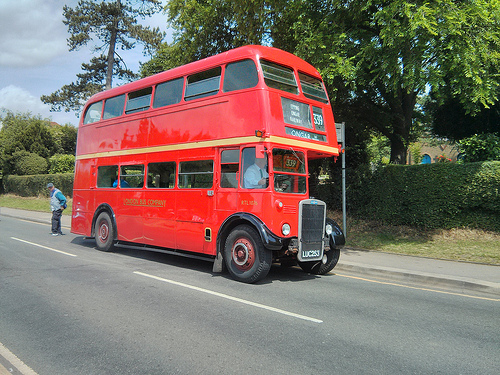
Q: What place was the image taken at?
A: It was taken at the road.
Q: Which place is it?
A: It is a road.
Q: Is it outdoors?
A: Yes, it is outdoors.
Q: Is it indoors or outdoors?
A: It is outdoors.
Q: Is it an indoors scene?
A: No, it is outdoors.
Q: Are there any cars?
A: No, there are no cars.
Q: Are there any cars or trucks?
A: No, there are no cars or trucks.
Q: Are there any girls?
A: No, there are no girls.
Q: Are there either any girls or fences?
A: No, there are no girls or fences.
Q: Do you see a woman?
A: No, there are no women.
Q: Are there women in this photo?
A: No, there are no women.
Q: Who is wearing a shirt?
A: The driver is wearing a shirt.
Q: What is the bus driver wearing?
A: The driver is wearing a shirt.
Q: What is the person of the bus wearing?
A: The driver is wearing a shirt.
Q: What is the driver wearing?
A: The driver is wearing a shirt.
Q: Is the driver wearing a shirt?
A: Yes, the driver is wearing a shirt.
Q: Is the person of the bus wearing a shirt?
A: Yes, the driver is wearing a shirt.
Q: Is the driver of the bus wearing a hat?
A: No, the driver is wearing a shirt.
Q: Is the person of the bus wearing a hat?
A: No, the driver is wearing a shirt.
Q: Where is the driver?
A: The driver is on the bus.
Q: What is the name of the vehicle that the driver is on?
A: The vehicle is a bus.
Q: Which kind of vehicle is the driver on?
A: The driver is on the bus.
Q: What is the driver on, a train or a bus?
A: The driver is on a bus.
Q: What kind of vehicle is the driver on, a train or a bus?
A: The driver is on a bus.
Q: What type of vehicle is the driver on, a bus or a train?
A: The driver is on a bus.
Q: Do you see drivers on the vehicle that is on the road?
A: Yes, there is a driver on the bus.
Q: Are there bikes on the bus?
A: No, there is a driver on the bus.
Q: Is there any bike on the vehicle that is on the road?
A: No, there is a driver on the bus.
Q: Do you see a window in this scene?
A: Yes, there is a window.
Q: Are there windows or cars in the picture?
A: Yes, there is a window.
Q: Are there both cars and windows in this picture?
A: No, there is a window but no cars.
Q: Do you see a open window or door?
A: Yes, there is an open window.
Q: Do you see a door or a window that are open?
A: Yes, the window is open.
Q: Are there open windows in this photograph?
A: Yes, there is an open window.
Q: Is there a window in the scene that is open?
A: Yes, there is a window that is open.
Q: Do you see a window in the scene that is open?
A: Yes, there is a window that is open.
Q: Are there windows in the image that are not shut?
A: Yes, there is a open window.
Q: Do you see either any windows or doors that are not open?
A: No, there is a window but it is open.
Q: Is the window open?
A: Yes, the window is open.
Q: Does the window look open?
A: Yes, the window is open.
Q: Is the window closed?
A: No, the window is open.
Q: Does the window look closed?
A: No, the window is open.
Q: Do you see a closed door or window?
A: No, there is a window but it is open.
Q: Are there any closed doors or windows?
A: No, there is a window but it is open.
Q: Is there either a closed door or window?
A: No, there is a window but it is open.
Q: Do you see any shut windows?
A: No, there is a window but it is open.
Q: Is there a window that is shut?
A: No, there is a window but it is open.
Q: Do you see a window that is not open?
A: No, there is a window but it is open.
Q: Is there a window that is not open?
A: No, there is a window but it is open.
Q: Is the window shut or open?
A: The window is open.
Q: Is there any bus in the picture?
A: Yes, there is a bus.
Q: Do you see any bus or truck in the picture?
A: Yes, there is a bus.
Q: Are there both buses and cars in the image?
A: No, there is a bus but no cars.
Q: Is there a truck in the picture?
A: No, there are no trucks.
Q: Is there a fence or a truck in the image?
A: No, there are no trucks or fences.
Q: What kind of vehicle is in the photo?
A: The vehicle is a bus.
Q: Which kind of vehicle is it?
A: The vehicle is a bus.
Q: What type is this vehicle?
A: This is a bus.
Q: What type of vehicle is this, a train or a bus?
A: This is a bus.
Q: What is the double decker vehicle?
A: The vehicle is a bus.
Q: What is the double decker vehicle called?
A: The vehicle is a bus.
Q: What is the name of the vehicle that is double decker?
A: The vehicle is a bus.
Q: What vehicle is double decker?
A: The vehicle is a bus.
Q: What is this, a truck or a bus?
A: This is a bus.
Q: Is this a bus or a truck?
A: This is a bus.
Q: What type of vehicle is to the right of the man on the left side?
A: The vehicle is a bus.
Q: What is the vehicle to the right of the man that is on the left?
A: The vehicle is a bus.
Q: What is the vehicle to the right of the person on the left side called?
A: The vehicle is a bus.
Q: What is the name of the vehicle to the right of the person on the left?
A: The vehicle is a bus.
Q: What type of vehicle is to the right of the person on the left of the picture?
A: The vehicle is a bus.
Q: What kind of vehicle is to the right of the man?
A: The vehicle is a bus.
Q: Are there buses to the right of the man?
A: Yes, there is a bus to the right of the man.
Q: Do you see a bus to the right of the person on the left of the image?
A: Yes, there is a bus to the right of the man.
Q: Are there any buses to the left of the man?
A: No, the bus is to the right of the man.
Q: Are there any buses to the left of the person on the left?
A: No, the bus is to the right of the man.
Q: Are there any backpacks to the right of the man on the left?
A: No, there is a bus to the right of the man.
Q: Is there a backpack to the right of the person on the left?
A: No, there is a bus to the right of the man.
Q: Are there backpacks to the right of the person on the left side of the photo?
A: No, there is a bus to the right of the man.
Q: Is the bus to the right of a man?
A: Yes, the bus is to the right of a man.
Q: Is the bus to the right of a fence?
A: No, the bus is to the right of a man.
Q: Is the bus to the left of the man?
A: No, the bus is to the right of the man.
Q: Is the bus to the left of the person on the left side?
A: No, the bus is to the right of the man.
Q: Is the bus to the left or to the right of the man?
A: The bus is to the right of the man.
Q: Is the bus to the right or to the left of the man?
A: The bus is to the right of the man.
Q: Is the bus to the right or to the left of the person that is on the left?
A: The bus is to the right of the man.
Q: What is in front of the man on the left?
A: The bus is in front of the man.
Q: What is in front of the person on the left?
A: The bus is in front of the man.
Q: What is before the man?
A: The bus is in front of the man.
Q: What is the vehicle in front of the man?
A: The vehicle is a bus.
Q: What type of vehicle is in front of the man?
A: The vehicle is a bus.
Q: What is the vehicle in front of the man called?
A: The vehicle is a bus.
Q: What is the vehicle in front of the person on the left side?
A: The vehicle is a bus.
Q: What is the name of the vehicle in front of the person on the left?
A: The vehicle is a bus.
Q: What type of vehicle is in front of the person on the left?
A: The vehicle is a bus.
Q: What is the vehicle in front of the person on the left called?
A: The vehicle is a bus.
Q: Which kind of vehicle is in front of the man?
A: The vehicle is a bus.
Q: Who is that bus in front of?
A: The bus is in front of the man.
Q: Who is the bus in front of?
A: The bus is in front of the man.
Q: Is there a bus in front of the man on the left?
A: Yes, there is a bus in front of the man.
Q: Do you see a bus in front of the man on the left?
A: Yes, there is a bus in front of the man.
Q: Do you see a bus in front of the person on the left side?
A: Yes, there is a bus in front of the man.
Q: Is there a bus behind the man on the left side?
A: No, the bus is in front of the man.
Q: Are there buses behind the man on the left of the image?
A: No, the bus is in front of the man.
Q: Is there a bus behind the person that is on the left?
A: No, the bus is in front of the man.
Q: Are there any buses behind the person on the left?
A: No, the bus is in front of the man.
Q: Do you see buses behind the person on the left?
A: No, the bus is in front of the man.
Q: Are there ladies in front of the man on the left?
A: No, there is a bus in front of the man.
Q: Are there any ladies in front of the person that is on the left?
A: No, there is a bus in front of the man.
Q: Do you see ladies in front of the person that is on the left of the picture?
A: No, there is a bus in front of the man.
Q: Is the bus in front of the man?
A: Yes, the bus is in front of the man.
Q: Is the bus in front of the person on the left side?
A: Yes, the bus is in front of the man.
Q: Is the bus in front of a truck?
A: No, the bus is in front of the man.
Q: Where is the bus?
A: The bus is on the road.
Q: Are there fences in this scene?
A: No, there are no fences.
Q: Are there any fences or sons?
A: No, there are no fences or sons.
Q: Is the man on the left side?
A: Yes, the man is on the left of the image.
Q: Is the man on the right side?
A: No, the man is on the left of the image.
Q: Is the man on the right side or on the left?
A: The man is on the left of the image.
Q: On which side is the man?
A: The man is on the left of the image.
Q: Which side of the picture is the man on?
A: The man is on the left of the image.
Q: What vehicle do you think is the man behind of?
A: The man is behind the bus.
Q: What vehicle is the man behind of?
A: The man is behind the bus.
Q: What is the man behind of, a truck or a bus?
A: The man is behind a bus.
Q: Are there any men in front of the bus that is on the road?
A: No, the man is behind the bus.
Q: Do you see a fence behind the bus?
A: No, there is a man behind the bus.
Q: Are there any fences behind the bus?
A: No, there is a man behind the bus.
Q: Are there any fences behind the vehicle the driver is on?
A: No, there is a man behind the bus.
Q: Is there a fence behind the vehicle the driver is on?
A: No, there is a man behind the bus.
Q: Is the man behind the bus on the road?
A: Yes, the man is behind the bus.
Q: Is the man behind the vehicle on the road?
A: Yes, the man is behind the bus.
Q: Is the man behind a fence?
A: No, the man is behind the bus.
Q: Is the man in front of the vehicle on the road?
A: No, the man is behind the bus.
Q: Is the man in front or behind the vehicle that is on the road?
A: The man is behind the bus.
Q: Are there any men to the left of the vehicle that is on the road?
A: Yes, there is a man to the left of the bus.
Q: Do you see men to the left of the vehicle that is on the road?
A: Yes, there is a man to the left of the bus.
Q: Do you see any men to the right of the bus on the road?
A: No, the man is to the left of the bus.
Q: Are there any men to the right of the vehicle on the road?
A: No, the man is to the left of the bus.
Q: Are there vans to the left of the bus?
A: No, there is a man to the left of the bus.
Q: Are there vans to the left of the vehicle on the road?
A: No, there is a man to the left of the bus.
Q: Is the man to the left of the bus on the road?
A: Yes, the man is to the left of the bus.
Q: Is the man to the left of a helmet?
A: No, the man is to the left of the bus.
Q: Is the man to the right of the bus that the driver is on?
A: No, the man is to the left of the bus.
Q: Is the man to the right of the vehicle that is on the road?
A: No, the man is to the left of the bus.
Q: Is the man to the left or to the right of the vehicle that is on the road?
A: The man is to the left of the bus.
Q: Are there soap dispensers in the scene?
A: No, there are no soap dispensers.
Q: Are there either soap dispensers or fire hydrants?
A: No, there are no soap dispensers or fire hydrants.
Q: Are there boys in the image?
A: No, there are no boys.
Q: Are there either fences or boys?
A: No, there are no boys or fences.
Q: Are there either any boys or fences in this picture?
A: No, there are no boys or fences.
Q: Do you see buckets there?
A: No, there are no buckets.